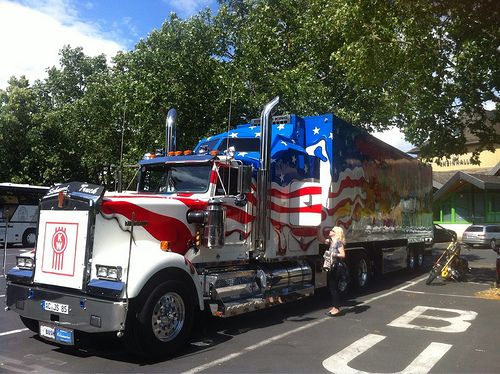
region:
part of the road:
[338, 310, 465, 369]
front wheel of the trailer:
[131, 278, 188, 350]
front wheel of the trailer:
[141, 160, 198, 189]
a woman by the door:
[319, 217, 350, 329]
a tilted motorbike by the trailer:
[408, 215, 474, 292]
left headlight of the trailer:
[88, 256, 122, 286]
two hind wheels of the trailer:
[404, 248, 422, 267]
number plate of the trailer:
[38, 298, 79, 343]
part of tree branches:
[303, 12, 466, 120]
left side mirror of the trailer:
[229, 163, 254, 204]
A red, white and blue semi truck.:
[9, 79, 444, 362]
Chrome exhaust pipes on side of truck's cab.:
[254, 88, 285, 253]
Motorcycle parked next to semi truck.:
[424, 231, 474, 288]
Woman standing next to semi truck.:
[313, 216, 363, 321]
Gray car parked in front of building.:
[461, 218, 499, 250]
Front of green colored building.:
[435, 166, 498, 225]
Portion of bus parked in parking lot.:
[3, 171, 43, 258]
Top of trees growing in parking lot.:
[0, 32, 216, 185]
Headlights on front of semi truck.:
[88, 257, 131, 284]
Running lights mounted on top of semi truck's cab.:
[143, 143, 228, 163]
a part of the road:
[382, 285, 463, 365]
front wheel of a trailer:
[143, 290, 191, 338]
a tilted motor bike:
[432, 231, 473, 283]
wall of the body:
[331, 135, 418, 223]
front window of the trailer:
[156, 161, 204, 201]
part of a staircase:
[214, 273, 272, 320]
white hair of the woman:
[336, 220, 346, 242]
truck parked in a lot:
[4, 90, 468, 367]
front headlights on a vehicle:
[88, 257, 133, 284]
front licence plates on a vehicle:
[35, 317, 77, 351]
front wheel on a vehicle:
[124, 267, 209, 362]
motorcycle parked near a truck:
[416, 228, 484, 290]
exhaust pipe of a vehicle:
[242, 90, 289, 267]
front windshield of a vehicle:
[132, 155, 220, 197]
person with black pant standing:
[307, 218, 357, 320]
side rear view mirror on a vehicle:
[222, 153, 257, 210]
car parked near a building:
[456, 218, 498, 255]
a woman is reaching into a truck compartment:
[318, 218, 353, 320]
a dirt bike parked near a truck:
[427, 231, 472, 286]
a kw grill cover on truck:
[38, 208, 86, 287]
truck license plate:
[32, 292, 77, 319]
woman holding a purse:
[320, 246, 337, 271]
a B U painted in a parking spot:
[317, 301, 487, 371]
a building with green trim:
[433, 167, 499, 227]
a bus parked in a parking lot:
[1, 178, 54, 246]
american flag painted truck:
[6, 124, 439, 344]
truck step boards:
[199, 265, 276, 318]